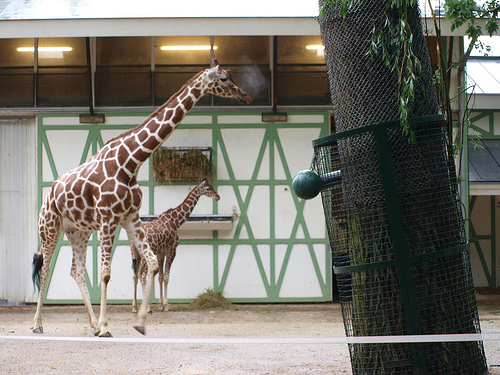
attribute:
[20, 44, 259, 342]
giraffe — walking, alone, brown, white, penned, captive, tailed, standing, enclosed, eating, spotted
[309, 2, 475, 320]
tree — caged, netted, brown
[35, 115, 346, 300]
wall — green, tan, white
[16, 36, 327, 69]
lights — white, on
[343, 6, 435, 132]
moss — growing, green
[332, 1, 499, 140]
leaves — green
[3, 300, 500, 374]
ground — brown, tan, dirt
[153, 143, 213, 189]
basket — full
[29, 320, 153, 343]
hooves — grey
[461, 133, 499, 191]
roofing — metal, grey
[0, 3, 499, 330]
photo — taken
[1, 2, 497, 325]
building — white, green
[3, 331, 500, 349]
string — white